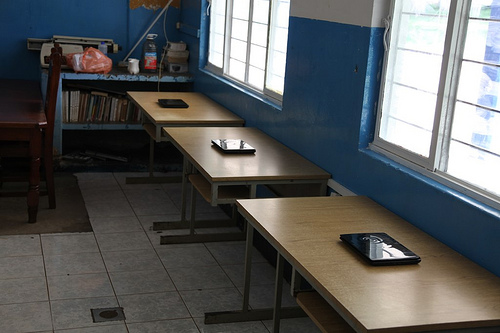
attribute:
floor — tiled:
[10, 173, 276, 330]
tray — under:
[170, 148, 215, 224]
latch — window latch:
[378, 13, 391, 54]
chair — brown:
[2, 39, 63, 210]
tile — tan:
[59, 223, 227, 307]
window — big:
[372, 7, 499, 189]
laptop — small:
[339, 229, 416, 270]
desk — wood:
[232, 197, 499, 331]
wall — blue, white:
[300, 61, 332, 122]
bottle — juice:
[141, 32, 160, 70]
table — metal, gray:
[201, 194, 498, 331]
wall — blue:
[1, 0, 170, 106]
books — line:
[64, 90, 125, 121]